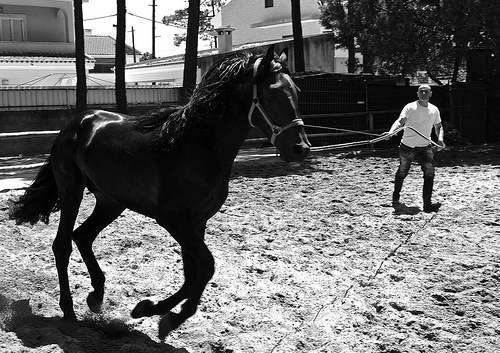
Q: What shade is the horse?
A: Black.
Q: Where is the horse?
A: Pen.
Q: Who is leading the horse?
A: The man.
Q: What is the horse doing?
A: Cantering.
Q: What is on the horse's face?
A: Bridal.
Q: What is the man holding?
A: Rope.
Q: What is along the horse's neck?
A: Mane.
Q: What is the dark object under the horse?
A: Shadow.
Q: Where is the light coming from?
A: Sun.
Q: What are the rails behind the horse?
A: Fence.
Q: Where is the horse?
A: Dirt ground enclosure.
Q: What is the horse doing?
A: Running.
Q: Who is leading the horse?
A: Man in blue jeans to the right of the horse.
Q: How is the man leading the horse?
A: By rope.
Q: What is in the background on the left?
A: Houses.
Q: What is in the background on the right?
A: Trees.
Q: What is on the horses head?
A: Harness.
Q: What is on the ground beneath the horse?
A: Shadow.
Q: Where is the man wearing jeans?
A: In the background with the rope.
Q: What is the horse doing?
A: Running.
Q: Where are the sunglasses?
A: On the man's face.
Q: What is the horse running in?
A: Dirt.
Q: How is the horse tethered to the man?
A: Rope.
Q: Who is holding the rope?
A: Man in sunglasses.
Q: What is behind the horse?
A: Fence.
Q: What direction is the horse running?
A: Right.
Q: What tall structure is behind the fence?
A: A house.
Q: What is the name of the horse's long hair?
A: Mane.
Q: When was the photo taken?
A: Daytime.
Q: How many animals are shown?
A: One.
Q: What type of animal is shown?
A: Horse.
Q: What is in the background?
A: Buldings.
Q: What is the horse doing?
A: Running.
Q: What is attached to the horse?
A: Rope.